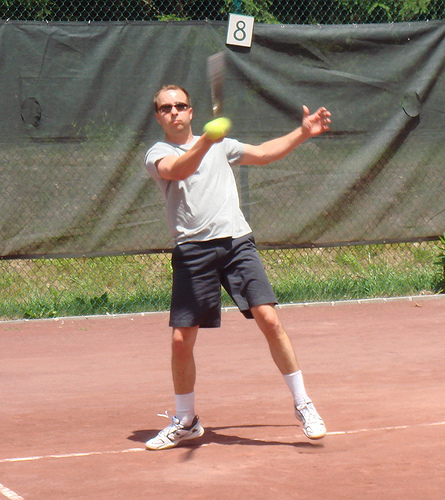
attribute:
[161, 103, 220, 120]
sunglasses — black 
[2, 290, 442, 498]
chalk — white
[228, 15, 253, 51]
number — black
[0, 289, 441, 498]
court — clay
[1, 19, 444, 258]
mesh — black 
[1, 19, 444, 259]
cloth background — pourous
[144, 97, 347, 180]
arms — raised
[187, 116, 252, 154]
ball — airborne, yellow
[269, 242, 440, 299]
grass — Green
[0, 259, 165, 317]
grass — Green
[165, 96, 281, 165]
ball — green 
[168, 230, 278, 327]
shorts — black 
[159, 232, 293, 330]
shorts — black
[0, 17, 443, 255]
cloth — dark 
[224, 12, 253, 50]
card — white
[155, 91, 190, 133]
face — goofy